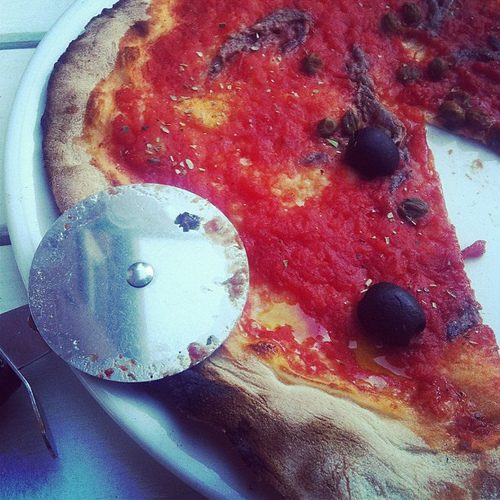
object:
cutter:
[0, 181, 250, 408]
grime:
[172, 212, 239, 257]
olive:
[348, 275, 425, 343]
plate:
[106, 396, 237, 498]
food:
[38, 3, 498, 496]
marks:
[342, 46, 380, 95]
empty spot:
[426, 126, 497, 308]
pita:
[35, 23, 491, 479]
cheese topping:
[82, 0, 484, 453]